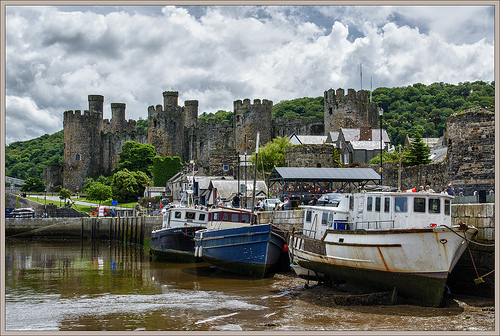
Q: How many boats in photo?
A: Three.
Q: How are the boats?
A: Parked.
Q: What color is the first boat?
A: White.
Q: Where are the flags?
A: On boats.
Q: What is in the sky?
A: Clouds.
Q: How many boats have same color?
A: Two.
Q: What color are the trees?
A: Green.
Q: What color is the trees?
A: Green.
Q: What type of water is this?
A: Murky.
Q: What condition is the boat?
A: Rusty.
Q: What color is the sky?
A: White.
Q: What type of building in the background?
A: Castles.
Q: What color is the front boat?
A: White.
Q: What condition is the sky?
A: Cloudy.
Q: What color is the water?
A: Green and brown.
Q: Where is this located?
A: Outside in harbor.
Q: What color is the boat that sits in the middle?
A: Blue.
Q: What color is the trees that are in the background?
A: Green.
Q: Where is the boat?
A: By the dock.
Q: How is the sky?
A: Cloudy.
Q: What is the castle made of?
A: Brick.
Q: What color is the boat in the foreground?
A: White.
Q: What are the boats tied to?
A: The dock.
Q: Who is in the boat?
A: Nobody.